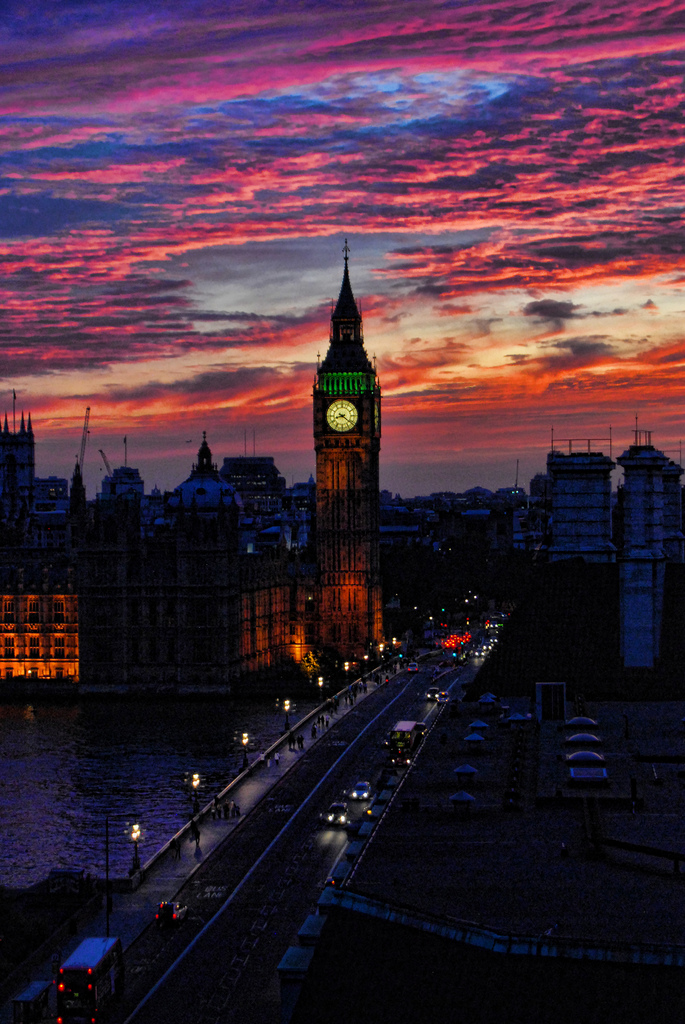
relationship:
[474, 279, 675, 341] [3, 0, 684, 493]
cloud in sky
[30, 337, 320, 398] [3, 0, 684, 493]
cloud in sky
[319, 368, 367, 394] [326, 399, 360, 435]
lights above clock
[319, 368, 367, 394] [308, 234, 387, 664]
lights on tower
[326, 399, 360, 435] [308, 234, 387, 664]
clock on tower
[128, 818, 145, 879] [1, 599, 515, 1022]
street light next to street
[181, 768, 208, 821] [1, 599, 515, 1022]
street light next to street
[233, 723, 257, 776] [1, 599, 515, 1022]
street light next to street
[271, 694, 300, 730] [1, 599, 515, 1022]
street light next to street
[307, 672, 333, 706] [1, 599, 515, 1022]
street light next to street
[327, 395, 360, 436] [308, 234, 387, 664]
clock on tower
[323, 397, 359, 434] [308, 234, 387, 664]
clock face adorning tower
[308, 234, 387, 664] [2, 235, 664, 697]
tower standing in city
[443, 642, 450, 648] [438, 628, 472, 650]
tail light seen in car group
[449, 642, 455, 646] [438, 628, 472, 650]
tail light seen in car group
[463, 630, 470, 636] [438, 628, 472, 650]
tail light seen in car group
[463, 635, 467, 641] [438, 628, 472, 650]
tail light seen in car group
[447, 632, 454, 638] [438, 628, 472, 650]
tail light seen in car group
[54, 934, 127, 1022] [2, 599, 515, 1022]
bus traveling down road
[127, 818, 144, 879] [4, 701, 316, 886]
street light standing next to water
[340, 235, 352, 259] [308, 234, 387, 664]
pinnacle adorning tower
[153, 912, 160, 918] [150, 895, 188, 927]
light mounted on car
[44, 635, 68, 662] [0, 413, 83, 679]
window on building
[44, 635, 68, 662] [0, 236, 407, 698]
window on building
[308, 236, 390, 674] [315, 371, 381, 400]
clock tower has lights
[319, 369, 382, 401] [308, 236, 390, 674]
lights are on clock tower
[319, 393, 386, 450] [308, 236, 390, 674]
clocks are on clock tower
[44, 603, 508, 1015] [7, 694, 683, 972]
street next to river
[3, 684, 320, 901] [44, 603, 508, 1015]
river next to street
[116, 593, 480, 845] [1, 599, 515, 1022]
lights are along street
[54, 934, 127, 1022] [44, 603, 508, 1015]
bus on street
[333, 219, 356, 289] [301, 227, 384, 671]
spire on clock tower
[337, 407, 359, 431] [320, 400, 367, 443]
hands are on clock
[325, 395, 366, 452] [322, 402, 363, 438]
clock has numerals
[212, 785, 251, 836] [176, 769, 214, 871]
people next to street lamp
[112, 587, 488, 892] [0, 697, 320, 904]
street lamps are next to water